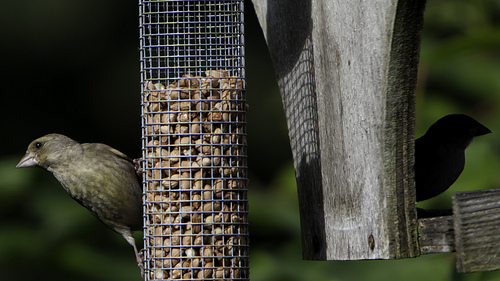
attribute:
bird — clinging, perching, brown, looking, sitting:
[15, 131, 145, 275]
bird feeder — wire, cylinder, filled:
[137, 1, 249, 279]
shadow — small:
[408, 109, 492, 204]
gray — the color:
[253, 2, 421, 260]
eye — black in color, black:
[32, 140, 45, 152]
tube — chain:
[136, 1, 249, 280]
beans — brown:
[141, 68, 246, 280]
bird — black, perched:
[412, 113, 490, 203]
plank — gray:
[249, 2, 430, 262]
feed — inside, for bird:
[142, 69, 246, 280]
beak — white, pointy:
[15, 151, 36, 168]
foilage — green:
[1, 3, 498, 279]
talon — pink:
[135, 251, 148, 276]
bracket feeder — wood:
[416, 184, 497, 271]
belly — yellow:
[87, 167, 127, 209]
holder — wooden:
[418, 209, 456, 254]